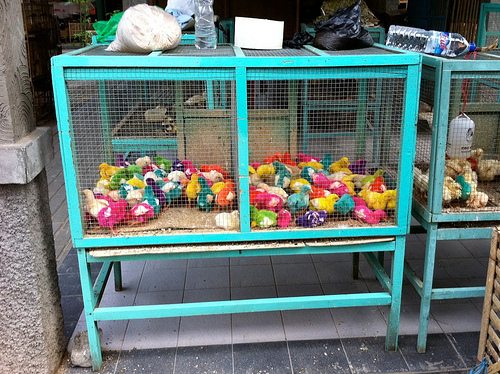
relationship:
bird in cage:
[80, 182, 106, 218] [47, 40, 422, 369]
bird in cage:
[215, 209, 240, 231] [47, 40, 422, 369]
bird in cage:
[274, 208, 293, 228] [47, 40, 422, 369]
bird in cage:
[294, 208, 328, 230] [47, 40, 422, 369]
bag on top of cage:
[309, 2, 373, 51] [47, 40, 422, 369]